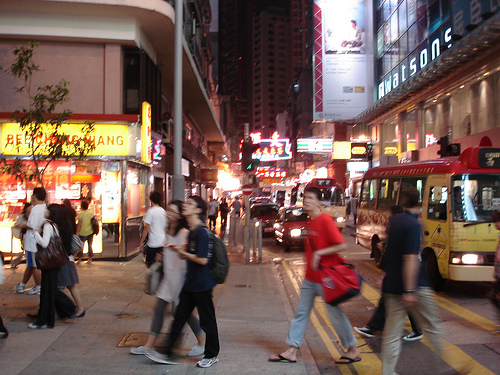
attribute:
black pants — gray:
[152, 283, 220, 361]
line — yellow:
[437, 289, 498, 341]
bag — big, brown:
[34, 222, 70, 270]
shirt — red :
[303, 213, 349, 283]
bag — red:
[312, 250, 367, 311]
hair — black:
[184, 190, 211, 220]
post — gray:
[243, 198, 252, 258]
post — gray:
[256, 217, 266, 263]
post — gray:
[248, 216, 258, 259]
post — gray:
[227, 214, 239, 249]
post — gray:
[234, 215, 245, 255]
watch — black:
[402, 289, 416, 295]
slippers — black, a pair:
[263, 343, 363, 372]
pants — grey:
[285, 279, 360, 350]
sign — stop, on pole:
[243, 182, 253, 197]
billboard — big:
[310, 0, 379, 127]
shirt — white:
[154, 228, 191, 309]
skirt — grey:
[67, 265, 74, 283]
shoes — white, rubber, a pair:
[12, 275, 44, 299]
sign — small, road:
[215, 131, 311, 196]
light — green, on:
[303, 2, 443, 111]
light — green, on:
[1, 87, 181, 264]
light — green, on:
[204, 160, 244, 197]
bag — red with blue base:
[284, 220, 366, 307]